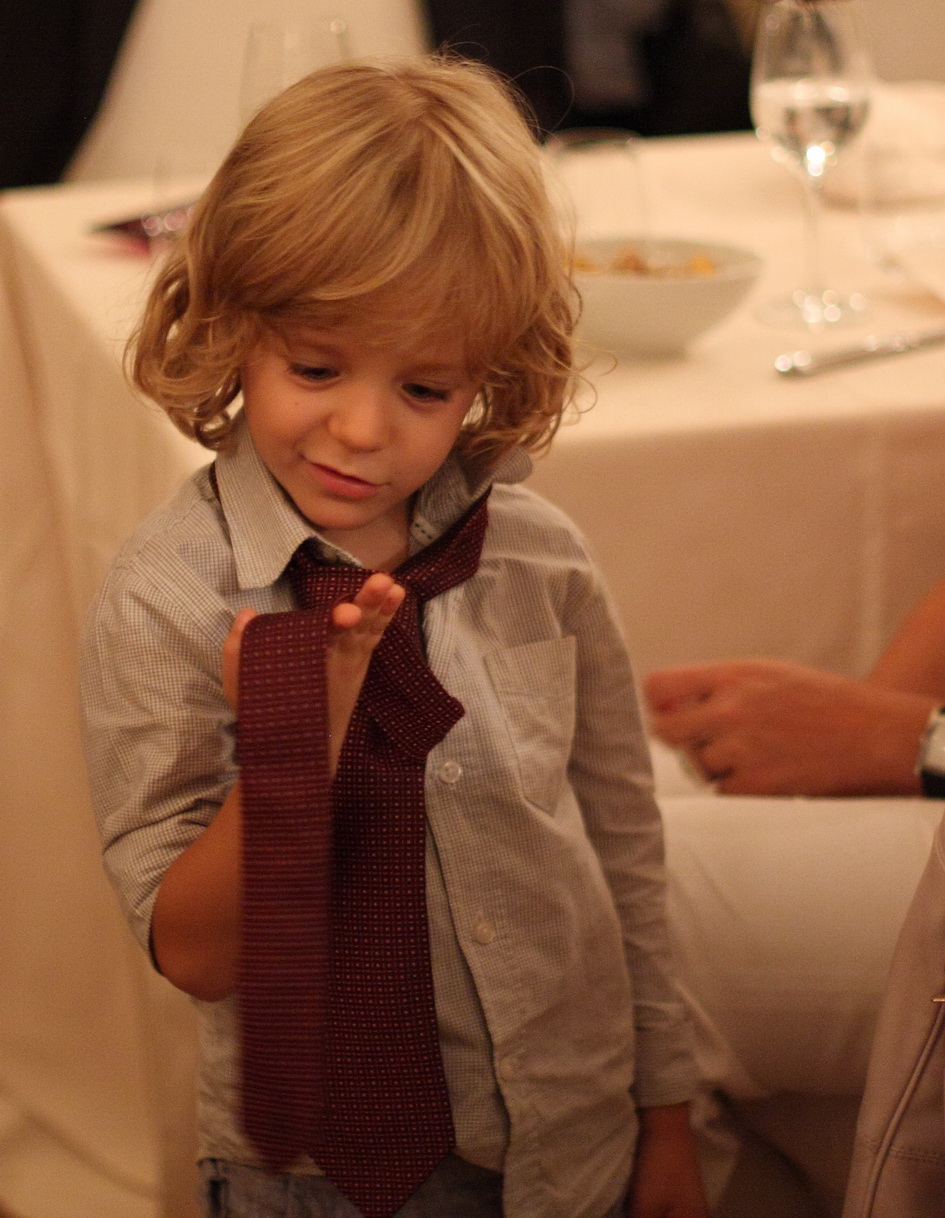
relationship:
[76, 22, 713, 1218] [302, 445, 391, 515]
boy has mouth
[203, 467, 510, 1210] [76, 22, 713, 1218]
tie worn by boy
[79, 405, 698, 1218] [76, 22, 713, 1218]
shirt worn by boy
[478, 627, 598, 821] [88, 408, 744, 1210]
pocket attached to shirt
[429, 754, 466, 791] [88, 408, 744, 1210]
button attached to shirt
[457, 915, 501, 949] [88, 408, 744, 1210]
button attached to shirt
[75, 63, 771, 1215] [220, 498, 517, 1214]
boy wearing tie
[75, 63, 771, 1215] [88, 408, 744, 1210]
boy has shirt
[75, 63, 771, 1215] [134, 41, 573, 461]
boy has hair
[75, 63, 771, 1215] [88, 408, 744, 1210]
boy wears shirt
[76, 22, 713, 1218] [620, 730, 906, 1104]
boy has pants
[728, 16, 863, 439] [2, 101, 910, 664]
glass on table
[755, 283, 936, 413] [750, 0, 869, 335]
knife under glass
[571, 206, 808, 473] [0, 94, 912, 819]
bowl on table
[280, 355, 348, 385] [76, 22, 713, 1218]
eye on boy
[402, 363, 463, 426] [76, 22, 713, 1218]
eye on boy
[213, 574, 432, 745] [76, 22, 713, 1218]
hand on boy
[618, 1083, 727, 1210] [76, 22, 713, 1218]
hand on boy